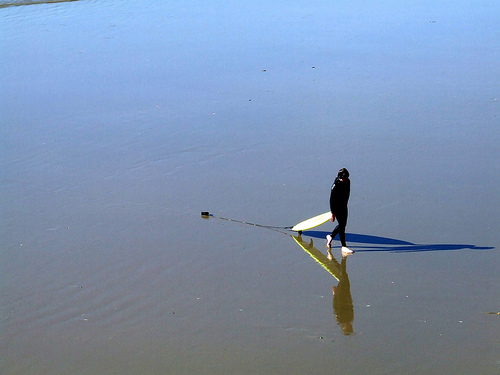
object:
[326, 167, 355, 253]
person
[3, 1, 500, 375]
watered area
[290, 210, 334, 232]
surfboard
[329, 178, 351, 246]
wet suit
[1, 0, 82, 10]
land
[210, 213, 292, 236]
rope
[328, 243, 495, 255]
reflection of person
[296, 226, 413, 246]
shadow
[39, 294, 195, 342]
sand ripples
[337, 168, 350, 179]
hair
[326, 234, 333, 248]
foot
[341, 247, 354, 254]
foot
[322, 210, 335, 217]
top